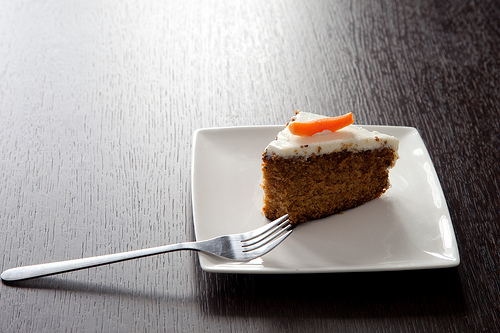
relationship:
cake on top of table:
[264, 113, 395, 225] [2, 0, 499, 329]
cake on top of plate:
[264, 113, 395, 225] [191, 123, 461, 268]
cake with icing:
[264, 113, 395, 225] [266, 110, 400, 154]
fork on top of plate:
[2, 214, 292, 278] [191, 123, 461, 268]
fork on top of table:
[2, 214, 292, 278] [2, 0, 499, 329]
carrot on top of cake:
[290, 110, 354, 133] [264, 113, 395, 225]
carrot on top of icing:
[290, 110, 354, 133] [266, 110, 400, 154]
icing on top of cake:
[266, 110, 400, 154] [264, 113, 395, 225]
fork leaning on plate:
[2, 214, 292, 278] [191, 123, 461, 268]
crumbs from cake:
[294, 138, 389, 155] [264, 113, 395, 225]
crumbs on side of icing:
[294, 138, 389, 155] [266, 110, 400, 154]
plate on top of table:
[191, 123, 461, 268] [2, 0, 499, 329]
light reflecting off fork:
[224, 229, 288, 255] [2, 214, 292, 278]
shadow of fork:
[43, 279, 202, 310] [2, 214, 292, 278]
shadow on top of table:
[43, 279, 202, 310] [2, 0, 499, 329]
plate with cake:
[191, 123, 461, 268] [264, 113, 395, 225]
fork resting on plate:
[2, 214, 292, 278] [191, 123, 461, 268]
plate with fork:
[191, 123, 461, 268] [2, 214, 292, 278]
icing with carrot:
[266, 110, 400, 154] [290, 110, 354, 133]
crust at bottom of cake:
[270, 198, 368, 224] [264, 113, 395, 225]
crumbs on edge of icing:
[294, 138, 389, 155] [266, 110, 400, 154]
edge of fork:
[0, 267, 15, 282] [2, 214, 292, 278]